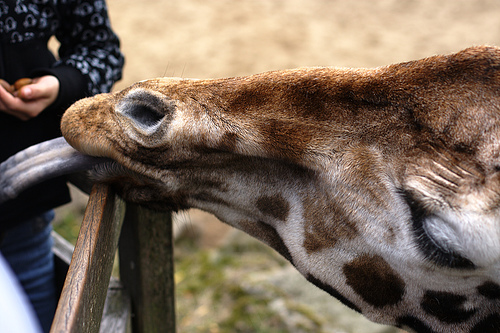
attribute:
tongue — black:
[1, 143, 119, 215]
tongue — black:
[5, 128, 99, 206]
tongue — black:
[0, 135, 88, 198]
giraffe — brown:
[0, 45, 499, 329]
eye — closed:
[390, 181, 480, 271]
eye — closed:
[395, 185, 483, 274]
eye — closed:
[396, 182, 477, 273]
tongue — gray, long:
[2, 135, 92, 201]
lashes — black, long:
[393, 184, 476, 271]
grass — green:
[57, 200, 407, 331]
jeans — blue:
[3, 210, 52, 331]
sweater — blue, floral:
[2, 1, 125, 213]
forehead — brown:
[164, 47, 499, 191]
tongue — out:
[0, 136, 96, 197]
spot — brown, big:
[298, 174, 364, 258]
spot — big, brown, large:
[341, 250, 406, 310]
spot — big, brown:
[422, 289, 480, 323]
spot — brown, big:
[237, 178, 293, 230]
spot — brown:
[335, 248, 411, 320]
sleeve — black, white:
[42, 8, 130, 112]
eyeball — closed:
[411, 193, 478, 269]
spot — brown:
[343, 247, 403, 310]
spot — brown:
[255, 190, 293, 225]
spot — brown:
[412, 283, 480, 325]